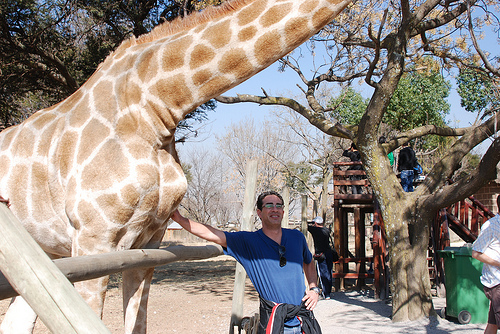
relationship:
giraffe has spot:
[3, 2, 371, 332] [219, 47, 257, 78]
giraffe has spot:
[3, 2, 371, 332] [203, 17, 233, 50]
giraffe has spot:
[3, 2, 371, 332] [150, 73, 197, 109]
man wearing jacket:
[174, 189, 327, 331] [222, 228, 312, 327]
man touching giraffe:
[174, 189, 327, 331] [3, 2, 371, 332]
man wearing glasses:
[174, 189, 327, 331] [259, 201, 284, 209]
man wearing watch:
[174, 189, 327, 331] [309, 287, 322, 295]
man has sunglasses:
[174, 189, 327, 331] [273, 243, 289, 268]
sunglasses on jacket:
[273, 243, 289, 268] [222, 228, 312, 327]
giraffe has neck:
[3, 2, 371, 332] [112, 2, 370, 127]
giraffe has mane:
[3, 2, 371, 332] [113, 0, 257, 50]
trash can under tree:
[434, 247, 494, 323] [215, 8, 500, 324]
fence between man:
[1, 161, 344, 332] [174, 189, 327, 331]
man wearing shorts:
[475, 196, 500, 327] [484, 282, 499, 324]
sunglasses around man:
[273, 243, 289, 268] [174, 189, 327, 331]